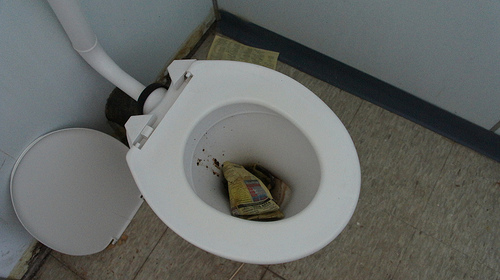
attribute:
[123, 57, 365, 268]
toilet — here, white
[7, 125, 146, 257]
seat cover — broken, white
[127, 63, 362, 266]
seat — white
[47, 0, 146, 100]
pipe — here, for water, white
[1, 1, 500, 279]
room — here, tiled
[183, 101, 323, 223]
bowl — white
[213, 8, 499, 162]
base board — dark, black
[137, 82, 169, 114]
connector ring — black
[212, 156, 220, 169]
stain — brown, gross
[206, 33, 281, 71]
paper — yellow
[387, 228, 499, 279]
tile — tan, white, gray, speckled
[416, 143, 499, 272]
tile — tan, white, gray, speckled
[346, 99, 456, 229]
tile — tan, white, gray, speckled